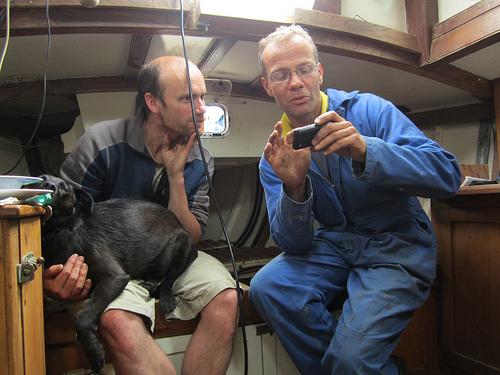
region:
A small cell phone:
[288, 120, 345, 154]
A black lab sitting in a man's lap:
[26, 171, 193, 370]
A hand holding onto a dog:
[43, 250, 95, 307]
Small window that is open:
[204, 105, 237, 144]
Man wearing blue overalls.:
[246, 26, 448, 373]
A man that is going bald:
[48, 50, 241, 373]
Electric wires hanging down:
[1, 2, 61, 174]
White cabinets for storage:
[106, 319, 338, 374]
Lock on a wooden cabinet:
[8, 245, 49, 303]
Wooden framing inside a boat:
[338, 9, 498, 84]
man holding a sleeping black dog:
[26, 54, 243, 374]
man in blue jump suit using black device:
[248, 24, 460, 374]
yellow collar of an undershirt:
[279, 90, 328, 145]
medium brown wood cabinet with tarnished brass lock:
[0, 203, 52, 373]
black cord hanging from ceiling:
[178, 1, 248, 373]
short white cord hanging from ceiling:
[0, 0, 10, 78]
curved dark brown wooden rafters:
[0, 6, 499, 131]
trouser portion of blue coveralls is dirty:
[249, 225, 437, 373]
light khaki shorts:
[68, 247, 243, 331]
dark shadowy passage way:
[200, 157, 271, 245]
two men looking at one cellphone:
[47, 20, 443, 328]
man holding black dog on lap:
[15, 47, 237, 347]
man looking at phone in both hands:
[245, 16, 370, 176]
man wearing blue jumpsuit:
[232, 7, 472, 357]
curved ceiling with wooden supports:
[7, 0, 483, 140]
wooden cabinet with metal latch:
[0, 181, 60, 366]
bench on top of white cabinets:
[15, 140, 437, 370]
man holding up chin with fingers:
[121, 50, 226, 185]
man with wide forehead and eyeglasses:
[255, 15, 330, 120]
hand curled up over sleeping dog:
[20, 154, 118, 313]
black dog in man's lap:
[30, 171, 192, 316]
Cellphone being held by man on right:
[285, 110, 340, 152]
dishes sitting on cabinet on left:
[5, 167, 51, 204]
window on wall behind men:
[207, 97, 230, 139]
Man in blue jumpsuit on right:
[251, 21, 463, 373]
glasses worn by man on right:
[260, 57, 322, 84]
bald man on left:
[129, 50, 217, 135]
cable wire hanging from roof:
[175, 11, 262, 371]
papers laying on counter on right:
[451, 165, 496, 187]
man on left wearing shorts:
[50, 50, 245, 370]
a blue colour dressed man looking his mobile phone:
[251, 20, 466, 257]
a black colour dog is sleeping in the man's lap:
[19, 164, 198, 366]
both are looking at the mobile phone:
[86, 17, 436, 367]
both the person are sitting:
[46, 19, 446, 371]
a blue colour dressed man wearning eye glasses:
[252, 14, 453, 351]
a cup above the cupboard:
[0, 166, 50, 191]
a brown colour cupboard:
[441, 183, 499, 353]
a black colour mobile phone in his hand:
[290, 127, 335, 152]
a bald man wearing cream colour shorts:
[59, 232, 247, 310]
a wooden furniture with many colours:
[7, 3, 496, 372]